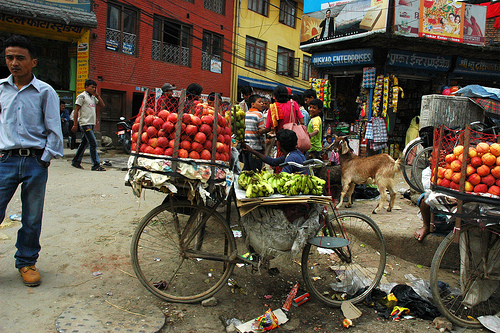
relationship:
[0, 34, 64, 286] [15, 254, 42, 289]
man standing on h left foot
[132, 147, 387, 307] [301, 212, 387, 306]
bicycle has a front wheel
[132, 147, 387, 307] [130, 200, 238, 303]
bicycle has a rear wheel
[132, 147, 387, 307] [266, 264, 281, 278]
bicycle has a foot pedal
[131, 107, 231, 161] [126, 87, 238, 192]
apples in a bicycle basket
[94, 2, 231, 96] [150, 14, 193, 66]
house has a balcony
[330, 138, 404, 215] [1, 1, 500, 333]
goat in market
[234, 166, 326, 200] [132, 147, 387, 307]
bananas on bicycle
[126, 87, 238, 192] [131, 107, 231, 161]
basket of apples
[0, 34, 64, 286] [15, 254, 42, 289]
man has a boot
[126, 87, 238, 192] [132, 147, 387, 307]
baskets on bicycle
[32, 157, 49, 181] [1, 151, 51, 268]
hand in pant pocket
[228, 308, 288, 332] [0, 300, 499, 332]
trash in street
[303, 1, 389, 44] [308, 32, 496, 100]
signs on building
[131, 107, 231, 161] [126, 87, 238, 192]
apples in basket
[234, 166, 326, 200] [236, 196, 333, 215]
bananas on cardboard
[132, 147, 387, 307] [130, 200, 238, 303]
bike has tires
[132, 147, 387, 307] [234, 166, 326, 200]
bike cart has bananas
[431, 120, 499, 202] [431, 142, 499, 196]
cart full of peaches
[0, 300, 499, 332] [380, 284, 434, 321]
ground has garbage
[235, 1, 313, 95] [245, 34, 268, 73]
building has windows